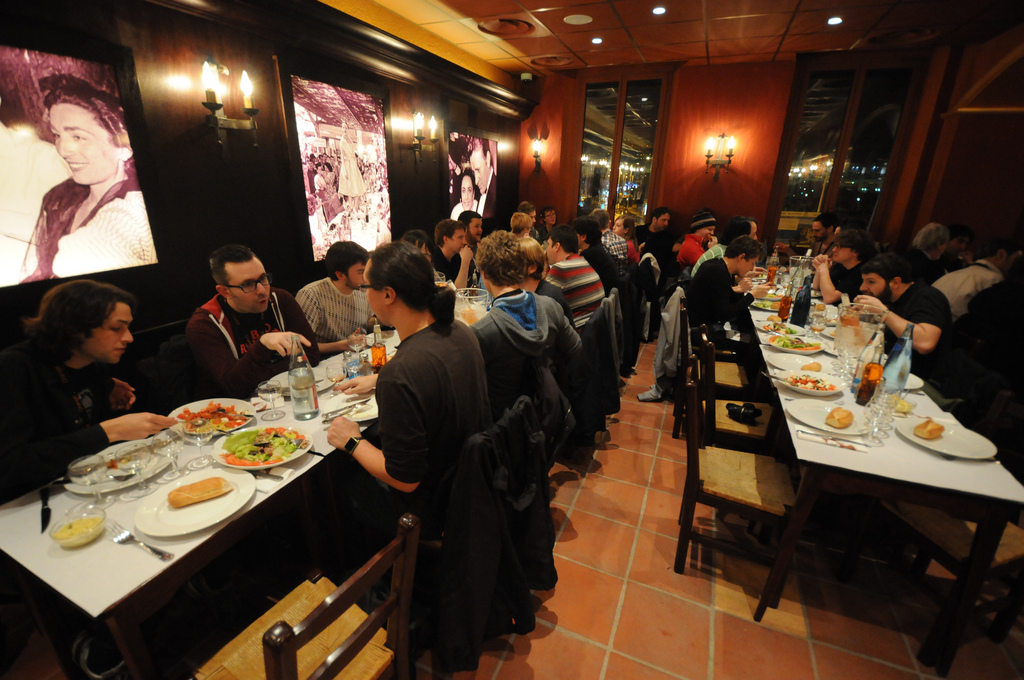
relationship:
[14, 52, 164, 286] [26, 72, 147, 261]
photo of a woman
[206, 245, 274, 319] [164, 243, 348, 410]
head of a man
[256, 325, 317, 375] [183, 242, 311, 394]
hand of man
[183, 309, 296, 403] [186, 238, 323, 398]
arm of man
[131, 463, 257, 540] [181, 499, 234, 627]
plate that white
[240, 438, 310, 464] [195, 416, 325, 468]
food on a plate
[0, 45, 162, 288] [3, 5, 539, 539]
photo on wall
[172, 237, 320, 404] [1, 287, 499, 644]
man sitting at table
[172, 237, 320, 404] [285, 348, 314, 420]
man touching glass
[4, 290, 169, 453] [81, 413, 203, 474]
woman with plate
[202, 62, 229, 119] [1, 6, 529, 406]
light on wall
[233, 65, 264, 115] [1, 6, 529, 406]
light on wall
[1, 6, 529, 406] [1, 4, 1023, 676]
wall in restaurant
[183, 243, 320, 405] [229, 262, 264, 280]
man has a forehead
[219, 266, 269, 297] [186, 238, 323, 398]
glasses of man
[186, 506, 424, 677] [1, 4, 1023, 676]
chair sitting inside restaurant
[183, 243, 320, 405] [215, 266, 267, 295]
man wearing glasses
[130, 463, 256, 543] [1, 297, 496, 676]
plate sitting on top of table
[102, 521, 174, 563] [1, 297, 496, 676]
silverware lying on top of table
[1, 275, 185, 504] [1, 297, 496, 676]
person sitting at table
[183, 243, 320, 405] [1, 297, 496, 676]
man sitting at table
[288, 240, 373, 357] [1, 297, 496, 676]
person sitting at table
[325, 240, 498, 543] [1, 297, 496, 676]
person sitting at table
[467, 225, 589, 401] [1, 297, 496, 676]
person sitting at table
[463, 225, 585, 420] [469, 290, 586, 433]
boy wearing hoodie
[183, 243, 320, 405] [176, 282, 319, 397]
man wearing hoodie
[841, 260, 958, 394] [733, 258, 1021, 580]
man at table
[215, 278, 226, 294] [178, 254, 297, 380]
ear of man